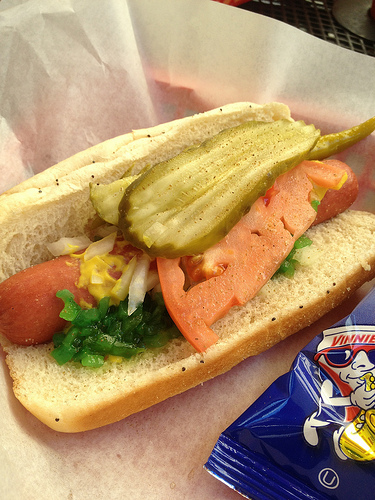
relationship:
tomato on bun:
[162, 163, 369, 339] [4, 99, 372, 436]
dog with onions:
[0, 158, 359, 347] [107, 258, 156, 306]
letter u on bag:
[320, 467, 337, 490] [298, 355, 354, 441]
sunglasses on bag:
[314, 343, 374, 367] [202, 285, 373, 498]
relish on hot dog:
[58, 283, 176, 362] [1, 96, 373, 434]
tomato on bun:
[156, 161, 347, 354] [5, 93, 372, 385]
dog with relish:
[0, 158, 359, 347] [34, 293, 176, 370]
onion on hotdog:
[127, 255, 151, 316] [1, 257, 57, 345]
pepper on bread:
[225, 202, 286, 268] [34, 100, 321, 396]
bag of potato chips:
[202, 285, 373, 498] [202, 294, 361, 497]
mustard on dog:
[82, 258, 111, 294] [76, 252, 130, 303]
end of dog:
[0, 272, 47, 344] [0, 158, 359, 347]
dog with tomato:
[0, 158, 359, 347] [163, 158, 336, 346]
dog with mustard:
[0, 158, 359, 347] [79, 252, 126, 303]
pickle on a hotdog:
[120, 117, 375, 258] [14, 171, 263, 340]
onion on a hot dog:
[47, 235, 93, 258] [5, 204, 174, 369]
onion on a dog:
[114, 254, 158, 310] [0, 158, 359, 347]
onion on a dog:
[47, 229, 138, 259] [0, 158, 359, 347]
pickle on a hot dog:
[112, 106, 374, 258] [0, 237, 140, 345]